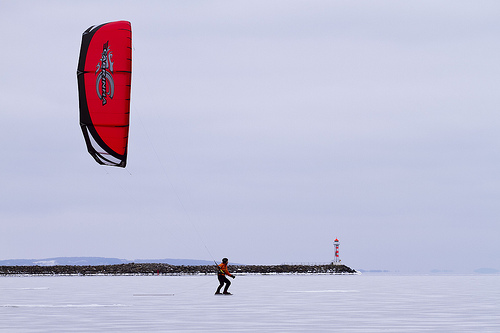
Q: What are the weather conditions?
A: It is overcast.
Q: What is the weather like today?
A: It is overcast.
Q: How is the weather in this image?
A: It is overcast.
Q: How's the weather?
A: It is overcast.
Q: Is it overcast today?
A: Yes, it is overcast.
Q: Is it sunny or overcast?
A: It is overcast.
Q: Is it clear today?
A: No, it is overcast.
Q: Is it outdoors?
A: Yes, it is outdoors.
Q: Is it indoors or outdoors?
A: It is outdoors.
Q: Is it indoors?
A: No, it is outdoors.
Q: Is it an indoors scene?
A: No, it is outdoors.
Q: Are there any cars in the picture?
A: No, there are no cars.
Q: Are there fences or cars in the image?
A: No, there are no cars or fences.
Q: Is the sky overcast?
A: Yes, the sky is overcast.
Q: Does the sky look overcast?
A: Yes, the sky is overcast.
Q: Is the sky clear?
A: No, the sky is overcast.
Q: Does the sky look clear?
A: No, the sky is overcast.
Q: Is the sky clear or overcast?
A: The sky is overcast.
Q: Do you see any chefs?
A: No, there are no chefs.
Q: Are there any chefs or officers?
A: No, there are no chefs or officers.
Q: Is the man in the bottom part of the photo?
A: Yes, the man is in the bottom of the image.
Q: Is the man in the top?
A: No, the man is in the bottom of the image.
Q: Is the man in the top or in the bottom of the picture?
A: The man is in the bottom of the image.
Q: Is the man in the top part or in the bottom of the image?
A: The man is in the bottom of the image.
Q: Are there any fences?
A: No, there are no fences.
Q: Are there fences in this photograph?
A: No, there are no fences.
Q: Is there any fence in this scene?
A: No, there are no fences.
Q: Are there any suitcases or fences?
A: No, there are no fences or suitcases.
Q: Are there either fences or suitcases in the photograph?
A: No, there are no fences or suitcases.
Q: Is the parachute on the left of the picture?
A: Yes, the parachute is on the left of the image.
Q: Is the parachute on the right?
A: No, the parachute is on the left of the image.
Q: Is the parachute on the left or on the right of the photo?
A: The parachute is on the left of the image.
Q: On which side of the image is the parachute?
A: The parachute is on the left of the image.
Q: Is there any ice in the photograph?
A: Yes, there is ice.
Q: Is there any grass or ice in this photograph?
A: Yes, there is ice.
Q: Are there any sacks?
A: No, there are no sacks.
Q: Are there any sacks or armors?
A: No, there are no sacks or armors.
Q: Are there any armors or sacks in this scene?
A: No, there are no sacks or armors.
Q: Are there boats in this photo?
A: No, there are no boats.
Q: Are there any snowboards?
A: No, there are no snowboards.